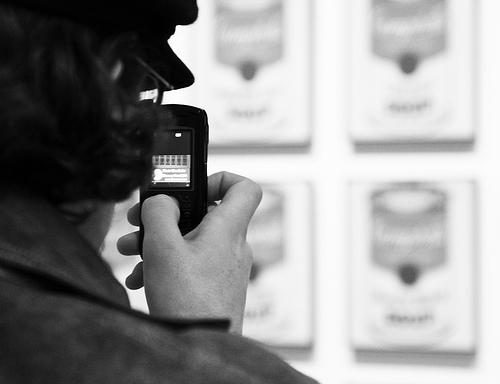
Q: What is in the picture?
A: Campbells can.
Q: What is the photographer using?
A: Cell phone.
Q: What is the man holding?
A: Flip phone.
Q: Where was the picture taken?
A: An art gallery.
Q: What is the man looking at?
A: Artwork.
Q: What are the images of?
A: Campbells soup can.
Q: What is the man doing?
A: Taking a picture.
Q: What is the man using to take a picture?
A: A phone.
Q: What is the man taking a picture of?
A: Artwork.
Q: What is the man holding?
A: A phone.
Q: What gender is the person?
A: A man.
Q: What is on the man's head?
A: A hat.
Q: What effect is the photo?
A: Black and white.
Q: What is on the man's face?
A: Glasses.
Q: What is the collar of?
A: A jacket.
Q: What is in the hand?
A: A cell phone.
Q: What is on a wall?
A: A sign.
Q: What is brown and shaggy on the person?
A: Hair.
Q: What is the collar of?
A: A person's shirt.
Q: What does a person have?
A: A hand.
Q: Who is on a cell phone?
A: A person.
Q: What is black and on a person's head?
A: A hat.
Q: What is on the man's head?
A: A hat.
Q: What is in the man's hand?
A: A cell phone.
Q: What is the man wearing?
A: A jacket.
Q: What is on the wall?
A: Frames of art.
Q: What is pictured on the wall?
A: Cans of soup.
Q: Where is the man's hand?
A: Holding the cell phone.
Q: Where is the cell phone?
A: In front of the man's face.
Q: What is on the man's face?
A: Eyeglasses.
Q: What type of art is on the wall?
A: Black and white.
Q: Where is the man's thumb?
A: On the button.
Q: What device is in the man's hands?
A: Cellphone.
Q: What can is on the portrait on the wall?
A: Campbell.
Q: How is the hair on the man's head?
A: Dark and curly.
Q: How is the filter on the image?
A: Black and white.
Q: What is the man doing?
A: Texting.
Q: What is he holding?
A: A phone.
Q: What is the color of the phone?
A: Black.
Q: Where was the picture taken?
A: Museum.